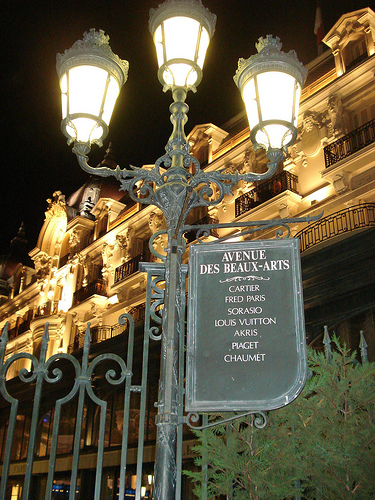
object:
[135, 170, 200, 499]
pole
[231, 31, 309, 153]
lights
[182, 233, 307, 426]
sign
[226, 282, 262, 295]
words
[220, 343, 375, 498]
bush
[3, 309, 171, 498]
fence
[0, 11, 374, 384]
building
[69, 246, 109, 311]
balcony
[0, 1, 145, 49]
sky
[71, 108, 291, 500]
lamp post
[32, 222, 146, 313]
details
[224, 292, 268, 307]
names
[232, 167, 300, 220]
railing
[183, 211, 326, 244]
bar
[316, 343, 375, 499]
branches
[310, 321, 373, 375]
fence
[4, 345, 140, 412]
metal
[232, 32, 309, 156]
lamp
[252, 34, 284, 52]
crown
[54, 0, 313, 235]
lamppost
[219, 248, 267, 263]
avenue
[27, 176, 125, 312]
facade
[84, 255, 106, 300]
windows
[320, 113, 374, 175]
railings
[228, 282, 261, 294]
word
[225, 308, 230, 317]
word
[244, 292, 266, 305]
word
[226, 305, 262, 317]
word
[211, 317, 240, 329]
word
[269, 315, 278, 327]
word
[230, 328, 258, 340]
word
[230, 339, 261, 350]
word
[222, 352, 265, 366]
word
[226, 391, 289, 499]
trees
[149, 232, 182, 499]
stand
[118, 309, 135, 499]
metal rails